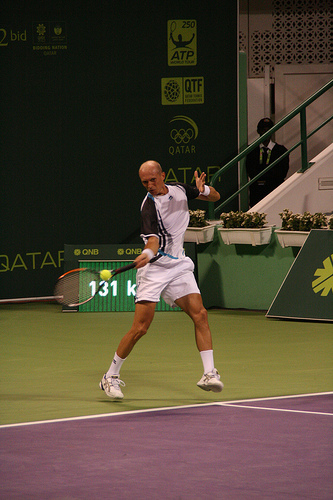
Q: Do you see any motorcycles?
A: No, there are no motorcycles.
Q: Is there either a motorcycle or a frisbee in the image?
A: No, there are no motorcycles or frisbees.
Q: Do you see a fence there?
A: No, there are no fences.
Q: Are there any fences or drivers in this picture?
A: No, there are no fences or drivers.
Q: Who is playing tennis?
A: The man is playing tennis.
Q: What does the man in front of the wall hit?
A: The man hits the tennis ball.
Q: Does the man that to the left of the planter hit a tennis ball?
A: Yes, the man hits a tennis ball.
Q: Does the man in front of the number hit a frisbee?
A: No, the man hits a tennis ball.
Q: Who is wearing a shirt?
A: The man is wearing a shirt.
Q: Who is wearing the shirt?
A: The man is wearing a shirt.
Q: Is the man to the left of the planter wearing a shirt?
A: Yes, the man is wearing a shirt.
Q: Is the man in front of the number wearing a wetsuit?
A: No, the man is wearing a shirt.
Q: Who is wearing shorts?
A: The man is wearing shorts.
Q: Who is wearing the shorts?
A: The man is wearing shorts.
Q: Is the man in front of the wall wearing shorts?
A: Yes, the man is wearing shorts.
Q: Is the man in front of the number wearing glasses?
A: No, the man is wearing shorts.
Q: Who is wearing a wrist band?
A: The man is wearing a wrist band.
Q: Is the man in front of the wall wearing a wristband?
A: Yes, the man is wearing a wristband.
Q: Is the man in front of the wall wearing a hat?
A: No, the man is wearing a wristband.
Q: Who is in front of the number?
A: The man is in front of the number.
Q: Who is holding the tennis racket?
A: The man is holding the tennis racket.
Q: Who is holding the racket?
A: The man is holding the tennis racket.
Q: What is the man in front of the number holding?
A: The man is holding the tennis racket.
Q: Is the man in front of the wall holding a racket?
A: Yes, the man is holding a racket.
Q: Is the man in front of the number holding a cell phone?
A: No, the man is holding a racket.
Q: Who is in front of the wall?
A: The man is in front of the wall.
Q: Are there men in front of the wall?
A: Yes, there is a man in front of the wall.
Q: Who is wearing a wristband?
A: The man is wearing a wristband.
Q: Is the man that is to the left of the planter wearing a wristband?
A: Yes, the man is wearing a wristband.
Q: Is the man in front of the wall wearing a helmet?
A: No, the man is wearing a wristband.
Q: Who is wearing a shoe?
A: The man is wearing a shoe.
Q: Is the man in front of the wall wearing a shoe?
A: Yes, the man is wearing a shoe.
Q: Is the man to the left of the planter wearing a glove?
A: No, the man is wearing a shoe.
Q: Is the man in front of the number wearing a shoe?
A: Yes, the man is wearing a shoe.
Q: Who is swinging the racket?
A: The man is swinging the racket.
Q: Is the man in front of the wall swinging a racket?
A: Yes, the man is swinging a racket.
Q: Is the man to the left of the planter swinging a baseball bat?
A: No, the man is swinging a racket.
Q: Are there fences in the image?
A: No, there are no fences.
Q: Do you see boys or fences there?
A: No, there are no fences or boys.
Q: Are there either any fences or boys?
A: No, there are no fences or boys.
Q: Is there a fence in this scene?
A: No, there are no fences.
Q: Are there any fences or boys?
A: No, there are no fences or boys.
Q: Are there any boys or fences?
A: No, there are no fences or boys.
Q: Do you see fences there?
A: No, there are no fences.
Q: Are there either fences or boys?
A: No, there are no fences or boys.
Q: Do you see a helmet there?
A: No, there are no helmets.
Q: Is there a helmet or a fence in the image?
A: No, there are no helmets or fences.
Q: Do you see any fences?
A: No, there are no fences.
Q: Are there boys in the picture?
A: No, there are no boys.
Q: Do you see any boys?
A: No, there are no boys.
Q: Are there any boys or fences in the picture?
A: No, there are no boys or fences.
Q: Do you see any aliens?
A: No, there are no aliens.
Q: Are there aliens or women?
A: No, there are no aliens or women.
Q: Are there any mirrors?
A: No, there are no mirrors.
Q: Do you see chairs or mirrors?
A: No, there are no mirrors or chairs.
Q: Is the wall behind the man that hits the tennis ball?
A: Yes, the wall is behind the man.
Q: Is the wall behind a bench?
A: No, the wall is behind the man.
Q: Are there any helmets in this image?
A: No, there are no helmets.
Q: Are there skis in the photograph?
A: No, there are no skis.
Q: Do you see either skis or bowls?
A: No, there are no skis or bowls.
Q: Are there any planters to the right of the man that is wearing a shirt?
A: Yes, there is a planter to the right of the man.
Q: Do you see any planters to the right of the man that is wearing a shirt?
A: Yes, there is a planter to the right of the man.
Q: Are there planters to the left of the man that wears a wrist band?
A: No, the planter is to the right of the man.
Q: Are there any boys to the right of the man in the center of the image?
A: No, there is a planter to the right of the man.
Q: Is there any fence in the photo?
A: No, there are no fences.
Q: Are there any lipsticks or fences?
A: No, there are no fences or lipsticks.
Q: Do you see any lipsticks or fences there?
A: No, there are no fences or lipsticks.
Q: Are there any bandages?
A: No, there are no bandages.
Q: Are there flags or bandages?
A: No, there are no bandages or flags.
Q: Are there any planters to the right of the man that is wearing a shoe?
A: Yes, there is a planter to the right of the man.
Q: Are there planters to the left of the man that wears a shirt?
A: No, the planter is to the right of the man.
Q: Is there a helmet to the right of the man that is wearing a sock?
A: No, there is a planter to the right of the man.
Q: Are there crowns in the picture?
A: No, there are no crowns.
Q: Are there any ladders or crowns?
A: No, there are no crowns or ladders.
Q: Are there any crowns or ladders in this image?
A: No, there are no crowns or ladders.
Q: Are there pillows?
A: No, there are no pillows.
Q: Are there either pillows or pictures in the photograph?
A: No, there are no pillows or pictures.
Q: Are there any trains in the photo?
A: No, there are no trains.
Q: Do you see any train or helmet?
A: No, there are no trains or helmets.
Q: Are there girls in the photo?
A: No, there are no girls.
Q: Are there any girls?
A: No, there are no girls.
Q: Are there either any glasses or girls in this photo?
A: No, there are no girls or glasses.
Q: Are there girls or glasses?
A: No, there are no girls or glasses.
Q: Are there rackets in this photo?
A: Yes, there is a racket.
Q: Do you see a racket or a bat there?
A: Yes, there is a racket.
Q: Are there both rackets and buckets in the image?
A: No, there is a racket but no buckets.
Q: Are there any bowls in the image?
A: No, there are no bowls.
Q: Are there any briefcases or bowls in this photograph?
A: No, there are no bowls or briefcases.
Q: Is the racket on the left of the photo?
A: Yes, the racket is on the left of the image.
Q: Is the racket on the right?
A: No, the racket is on the left of the image.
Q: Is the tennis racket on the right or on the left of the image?
A: The tennis racket is on the left of the image.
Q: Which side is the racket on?
A: The racket is on the left of the image.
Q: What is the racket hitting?
A: The racket is hitting the tennis ball.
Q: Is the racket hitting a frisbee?
A: No, the racket is hitting a tennis ball.